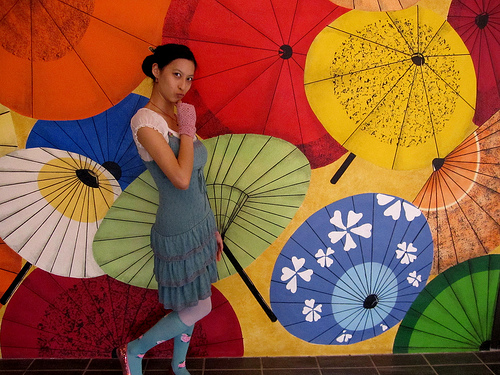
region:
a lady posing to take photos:
[136, 40, 211, 357]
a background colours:
[235, 50, 494, 335]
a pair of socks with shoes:
[121, 312, 191, 372]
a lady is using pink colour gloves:
[173, 96, 197, 141]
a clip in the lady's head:
[147, 43, 162, 56]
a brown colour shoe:
[113, 340, 130, 374]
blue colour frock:
[166, 196, 214, 287]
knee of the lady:
[192, 290, 210, 320]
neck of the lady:
[138, 95, 178, 115]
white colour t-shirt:
[131, 108, 168, 132]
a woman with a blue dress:
[140, 130, 220, 311]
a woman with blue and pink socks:
[125, 306, 195, 371]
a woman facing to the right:
[110, 40, 220, 370]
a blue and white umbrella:
[270, 190, 435, 340]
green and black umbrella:
[90, 130, 310, 287]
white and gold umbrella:
[0, 145, 120, 275]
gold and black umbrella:
[301, 6, 473, 167]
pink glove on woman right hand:
[170, 100, 195, 135]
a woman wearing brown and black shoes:
[110, 340, 130, 370]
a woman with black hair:
[141, 41, 196, 81]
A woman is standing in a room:
[46, 17, 431, 367]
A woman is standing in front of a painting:
[82, 16, 460, 371]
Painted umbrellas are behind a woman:
[61, 16, 441, 369]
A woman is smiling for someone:
[71, 21, 402, 366]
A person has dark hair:
[135, 35, 200, 101]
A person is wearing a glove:
[116, 30, 226, 217]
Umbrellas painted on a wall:
[253, 15, 484, 340]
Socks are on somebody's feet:
[115, 306, 220, 371]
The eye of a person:
[166, 65, 185, 82]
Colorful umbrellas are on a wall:
[237, 20, 474, 369]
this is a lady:
[114, 29, 218, 372]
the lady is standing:
[117, 30, 210, 373]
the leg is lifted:
[120, 310, 176, 373]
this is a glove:
[176, 100, 196, 135]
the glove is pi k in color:
[174, 103, 196, 133]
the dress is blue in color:
[158, 189, 202, 296]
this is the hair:
[157, 44, 174, 57]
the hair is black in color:
[159, 42, 181, 57]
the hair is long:
[158, 43, 178, 58]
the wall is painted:
[210, 31, 465, 369]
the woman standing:
[116, 40, 223, 374]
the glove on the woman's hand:
[176, 103, 198, 138]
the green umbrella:
[91, 132, 311, 324]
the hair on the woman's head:
[141, 42, 198, 72]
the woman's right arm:
[134, 102, 205, 190]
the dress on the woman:
[132, 106, 227, 311]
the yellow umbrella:
[304, 5, 479, 183]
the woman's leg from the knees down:
[115, 299, 218, 374]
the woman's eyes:
[173, 68, 194, 83]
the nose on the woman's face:
[177, 75, 189, 91]